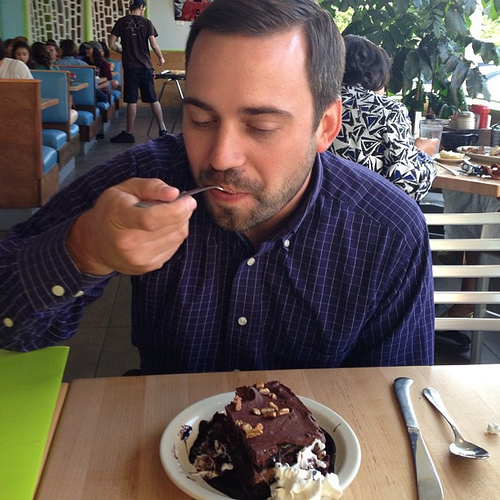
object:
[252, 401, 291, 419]
nuts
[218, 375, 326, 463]
brownie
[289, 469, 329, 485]
whipped cream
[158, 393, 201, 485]
plate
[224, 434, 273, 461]
frosting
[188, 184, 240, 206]
fork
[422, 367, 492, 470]
spoon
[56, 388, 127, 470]
table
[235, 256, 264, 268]
buttons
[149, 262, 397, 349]
shirt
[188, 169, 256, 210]
mouth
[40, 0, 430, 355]
man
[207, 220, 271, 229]
beard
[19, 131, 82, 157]
seats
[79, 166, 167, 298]
hand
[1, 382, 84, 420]
object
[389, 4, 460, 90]
plant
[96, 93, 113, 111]
chairs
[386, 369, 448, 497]
knife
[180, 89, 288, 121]
eyebrows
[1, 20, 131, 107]
people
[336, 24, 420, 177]
woman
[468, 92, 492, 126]
ketchup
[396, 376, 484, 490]
utensils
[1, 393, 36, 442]
menu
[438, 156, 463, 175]
wrapper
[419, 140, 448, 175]
paper